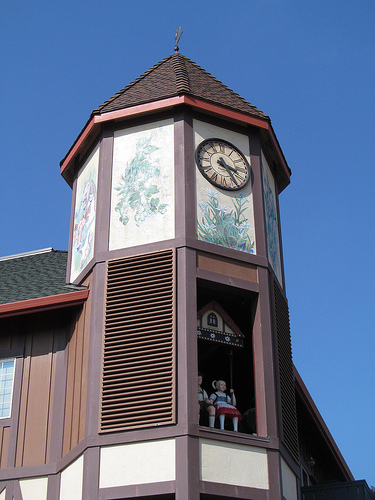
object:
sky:
[0, 0, 374, 494]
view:
[1, 4, 373, 493]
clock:
[191, 135, 252, 192]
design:
[112, 122, 170, 232]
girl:
[208, 377, 240, 429]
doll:
[209, 375, 239, 433]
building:
[0, 26, 374, 498]